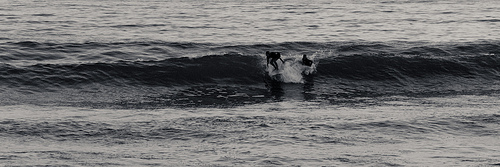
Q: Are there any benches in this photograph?
A: No, there are no benches.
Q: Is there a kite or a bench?
A: No, there are no benches or kites.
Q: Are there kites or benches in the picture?
A: No, there are no benches or kites.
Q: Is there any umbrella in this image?
A: No, there are no umbrellas.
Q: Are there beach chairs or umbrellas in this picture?
A: No, there are no umbrellas or beach chairs.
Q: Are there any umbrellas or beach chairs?
A: No, there are no umbrellas or beach chairs.